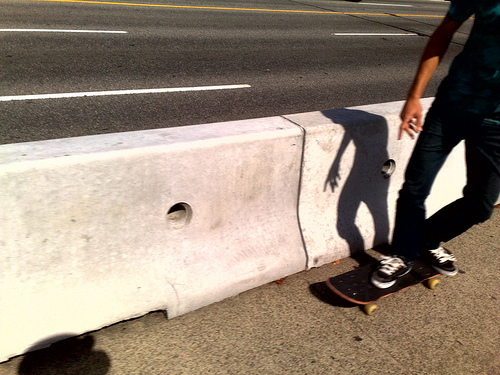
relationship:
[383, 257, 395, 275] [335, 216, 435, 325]
laces on shoes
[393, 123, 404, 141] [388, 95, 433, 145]
finger pointed out on hand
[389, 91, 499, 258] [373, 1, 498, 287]
jeans on skater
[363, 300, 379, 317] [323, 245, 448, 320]
wheel on skateboard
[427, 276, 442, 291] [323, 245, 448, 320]
wheel on skateboard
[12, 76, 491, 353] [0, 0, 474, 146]
barrier dividing street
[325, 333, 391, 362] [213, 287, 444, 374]
flecks in sidewalk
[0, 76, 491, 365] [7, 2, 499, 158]
barrier near street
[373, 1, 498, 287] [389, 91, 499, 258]
skater has on jeans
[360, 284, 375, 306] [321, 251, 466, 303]
tip of board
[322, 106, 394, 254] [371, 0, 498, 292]
shadow of guy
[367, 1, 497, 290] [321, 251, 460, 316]
skater skating on board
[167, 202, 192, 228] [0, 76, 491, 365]
hole in barrier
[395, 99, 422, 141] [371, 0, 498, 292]
hand of guy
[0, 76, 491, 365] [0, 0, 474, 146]
barrier on street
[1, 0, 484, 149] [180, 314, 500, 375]
lines on sidewalk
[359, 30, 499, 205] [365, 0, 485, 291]
arm of skater